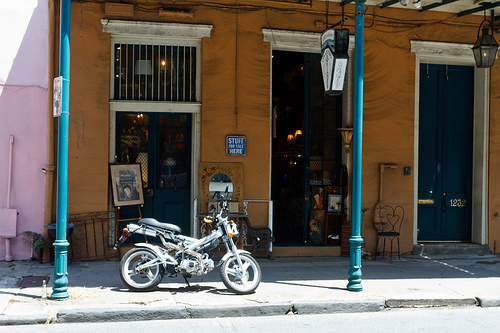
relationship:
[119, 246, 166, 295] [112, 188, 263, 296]
wheel of motorcyle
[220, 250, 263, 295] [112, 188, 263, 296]
wheel of motorcyle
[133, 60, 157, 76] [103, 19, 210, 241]
lampsade in windwo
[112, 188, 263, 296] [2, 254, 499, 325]
motorcyle on sidewalk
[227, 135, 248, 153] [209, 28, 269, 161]
sign on wall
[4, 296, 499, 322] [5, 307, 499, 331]
curb by road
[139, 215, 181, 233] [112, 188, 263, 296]
seat of motorcyle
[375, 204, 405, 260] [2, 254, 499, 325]
chair on sidewalk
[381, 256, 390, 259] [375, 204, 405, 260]
stopper stabilizes chair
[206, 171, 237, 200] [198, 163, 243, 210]
mirror has frame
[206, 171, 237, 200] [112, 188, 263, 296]
mirror reflects motorcyle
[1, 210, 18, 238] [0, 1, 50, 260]
fusebox on facade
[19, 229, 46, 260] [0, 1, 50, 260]
plant by facade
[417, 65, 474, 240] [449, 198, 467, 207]
door has number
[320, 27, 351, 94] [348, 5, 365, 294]
sign hangs on post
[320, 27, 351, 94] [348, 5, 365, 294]
sign on post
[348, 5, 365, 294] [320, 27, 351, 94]
post has sign